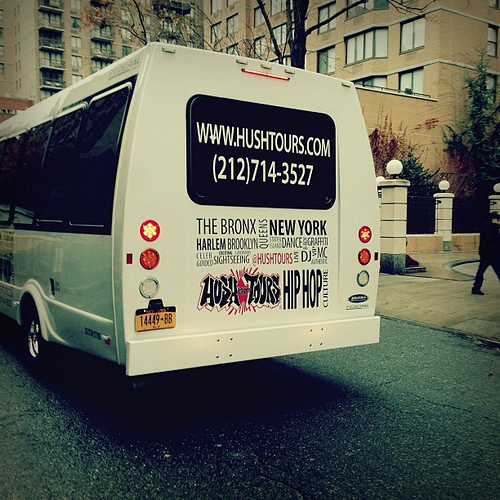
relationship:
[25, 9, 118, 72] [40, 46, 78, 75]
building has balconies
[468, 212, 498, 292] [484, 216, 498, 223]
person wearing hat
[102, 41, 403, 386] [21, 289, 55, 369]
bus has wheel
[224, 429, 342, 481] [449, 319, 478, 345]
road has edge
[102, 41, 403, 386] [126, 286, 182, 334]
bus has tag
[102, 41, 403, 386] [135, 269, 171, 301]
bus has light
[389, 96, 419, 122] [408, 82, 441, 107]
wall has edge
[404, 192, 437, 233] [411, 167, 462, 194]
fence has light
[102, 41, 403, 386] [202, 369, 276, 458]
bus has shadow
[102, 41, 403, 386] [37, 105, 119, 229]
bus has window